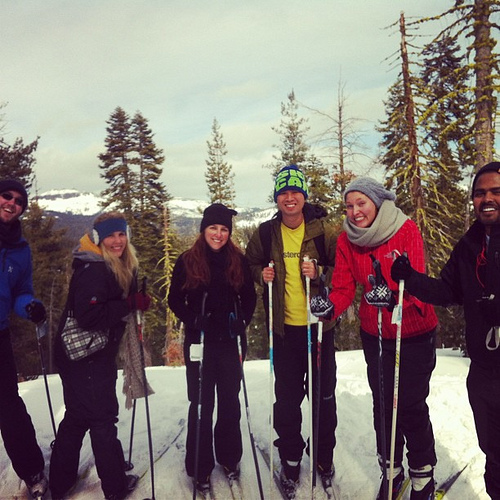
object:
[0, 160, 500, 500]
skiers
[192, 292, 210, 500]
post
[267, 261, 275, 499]
post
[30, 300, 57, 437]
post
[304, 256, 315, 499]
post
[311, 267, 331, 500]
post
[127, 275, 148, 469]
post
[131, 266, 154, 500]
post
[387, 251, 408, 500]
post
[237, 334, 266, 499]
post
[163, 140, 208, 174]
cloud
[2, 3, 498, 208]
sky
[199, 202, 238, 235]
beanie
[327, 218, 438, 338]
sweater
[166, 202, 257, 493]
woman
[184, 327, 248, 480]
pants